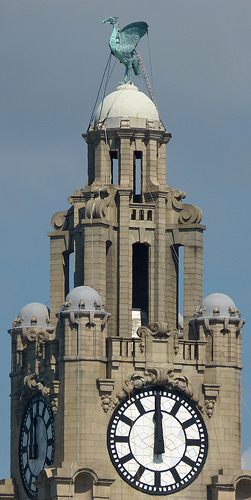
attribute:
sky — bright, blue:
[38, 125, 64, 166]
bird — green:
[104, 14, 152, 87]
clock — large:
[113, 382, 216, 491]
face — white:
[125, 412, 192, 477]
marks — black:
[173, 406, 177, 413]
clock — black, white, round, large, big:
[105, 387, 208, 495]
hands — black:
[154, 394, 165, 455]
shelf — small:
[203, 382, 220, 418]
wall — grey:
[63, 350, 110, 497]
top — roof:
[93, 65, 163, 135]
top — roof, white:
[87, 77, 168, 126]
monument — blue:
[101, 14, 151, 83]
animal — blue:
[103, 13, 148, 84]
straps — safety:
[83, 48, 112, 127]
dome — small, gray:
[194, 292, 242, 322]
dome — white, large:
[94, 81, 161, 123]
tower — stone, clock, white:
[12, 61, 237, 485]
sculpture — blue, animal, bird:
[101, 16, 151, 83]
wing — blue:
[120, 20, 149, 53]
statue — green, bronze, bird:
[103, 14, 148, 81]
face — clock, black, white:
[106, 389, 210, 495]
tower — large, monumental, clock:
[12, 9, 242, 486]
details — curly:
[136, 322, 181, 382]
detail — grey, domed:
[59, 285, 110, 320]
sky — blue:
[0, 0, 250, 477]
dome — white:
[92, 82, 159, 127]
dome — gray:
[10, 302, 49, 327]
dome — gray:
[54, 285, 108, 312]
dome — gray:
[188, 292, 245, 320]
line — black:
[170, 400, 181, 415]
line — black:
[182, 416, 197, 428]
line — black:
[186, 438, 201, 445]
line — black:
[181, 453, 196, 466]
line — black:
[169, 465, 180, 482]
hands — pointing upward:
[153, 393, 164, 454]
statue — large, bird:
[101, 14, 149, 85]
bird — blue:
[92, 10, 152, 76]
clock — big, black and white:
[100, 377, 210, 498]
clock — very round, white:
[95, 374, 209, 492]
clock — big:
[96, 381, 216, 496]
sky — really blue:
[3, 376, 11, 449]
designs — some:
[52, 305, 120, 332]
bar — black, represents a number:
[168, 397, 181, 416]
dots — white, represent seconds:
[161, 480, 180, 497]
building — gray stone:
[7, 287, 249, 499]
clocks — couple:
[12, 382, 219, 494]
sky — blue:
[12, 11, 243, 285]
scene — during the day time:
[14, 11, 241, 389]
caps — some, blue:
[6, 280, 243, 332]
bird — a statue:
[65, 11, 175, 140]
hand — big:
[140, 387, 167, 460]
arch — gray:
[55, 459, 112, 499]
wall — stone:
[211, 411, 235, 439]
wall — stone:
[211, 409, 233, 423]